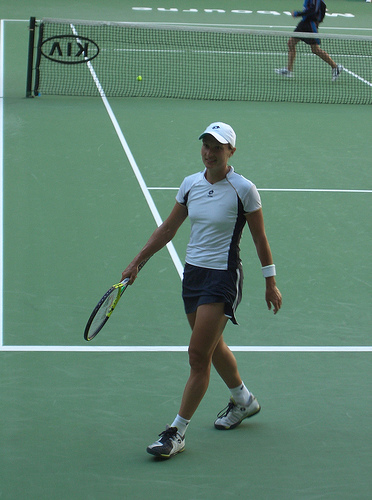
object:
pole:
[24, 14, 39, 96]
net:
[35, 15, 372, 105]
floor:
[0, 1, 372, 500]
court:
[0, 0, 372, 500]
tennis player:
[273, 1, 343, 82]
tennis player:
[119, 119, 284, 462]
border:
[41, 17, 371, 43]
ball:
[136, 74, 142, 82]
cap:
[198, 118, 237, 149]